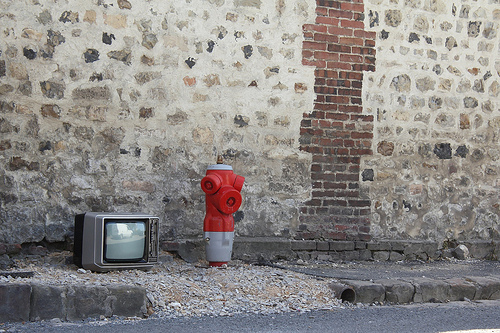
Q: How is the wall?
A: Old and dotty.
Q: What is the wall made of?
A: Bricks and plaster.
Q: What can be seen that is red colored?
A: A hydrant.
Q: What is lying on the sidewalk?
A: A discarded TV.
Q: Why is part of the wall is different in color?
A: It is made of smaller bricks and is not plastered.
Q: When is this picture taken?
A: During daytime.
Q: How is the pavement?
A: Old and broken at a point.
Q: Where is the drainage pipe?
A: Under the pavement opening on the road.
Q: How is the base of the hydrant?
A: Grey.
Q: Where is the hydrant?
A: On the wall.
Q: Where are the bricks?
A: On the wall.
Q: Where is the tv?
A: On the ground.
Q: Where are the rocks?
A: On the ground.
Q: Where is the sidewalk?
A: On the ground.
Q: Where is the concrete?
A: On the ground.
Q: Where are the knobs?
A: On the hydrant.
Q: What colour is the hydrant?
A: Red.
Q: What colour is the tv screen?
A: Gray.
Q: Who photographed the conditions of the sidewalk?
A: Concerned citizen.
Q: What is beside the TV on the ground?
A: Red and gray fire hydrant.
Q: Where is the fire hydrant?
A: On a damaged sidewalk.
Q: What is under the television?
A: Rocks.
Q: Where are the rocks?
A: Under the TV on the sidewalk.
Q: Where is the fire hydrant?
A: On the sidewalk.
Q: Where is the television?
A: Next to the hydrant.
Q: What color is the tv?
A: Gray and black.